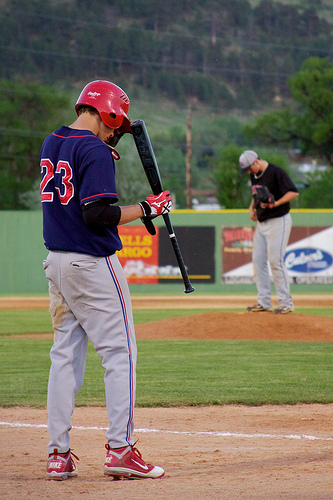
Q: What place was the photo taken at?
A: It was taken at the field.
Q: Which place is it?
A: It is a field.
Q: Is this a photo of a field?
A: Yes, it is showing a field.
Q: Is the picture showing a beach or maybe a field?
A: It is showing a field.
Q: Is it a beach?
A: No, it is a field.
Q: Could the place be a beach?
A: No, it is a field.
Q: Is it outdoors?
A: Yes, it is outdoors.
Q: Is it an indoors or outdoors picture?
A: It is outdoors.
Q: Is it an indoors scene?
A: No, it is outdoors.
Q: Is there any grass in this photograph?
A: Yes, there is grass.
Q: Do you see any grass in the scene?
A: Yes, there is grass.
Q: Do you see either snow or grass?
A: Yes, there is grass.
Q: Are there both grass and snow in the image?
A: No, there is grass but no snow.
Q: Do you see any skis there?
A: No, there are no skis.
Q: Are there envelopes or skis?
A: No, there are no skis or envelopes.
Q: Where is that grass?
A: The grass is on the ground.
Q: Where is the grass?
A: The grass is on the ground.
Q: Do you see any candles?
A: No, there are no candles.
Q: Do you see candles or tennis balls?
A: No, there are no candles or tennis balls.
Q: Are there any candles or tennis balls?
A: No, there are no candles or tennis balls.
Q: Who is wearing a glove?
A: The player is wearing a glove.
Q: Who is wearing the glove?
A: The player is wearing a glove.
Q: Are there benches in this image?
A: No, there are no benches.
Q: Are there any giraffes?
A: No, there are no giraffes.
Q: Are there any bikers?
A: No, there are no bikers.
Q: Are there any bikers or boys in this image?
A: No, there are no bikers or boys.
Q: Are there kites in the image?
A: No, there are no kites.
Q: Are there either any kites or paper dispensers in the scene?
A: No, there are no kites or paper dispensers.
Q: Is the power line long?
A: Yes, the power line is long.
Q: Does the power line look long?
A: Yes, the power line is long.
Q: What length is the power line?
A: The power line is long.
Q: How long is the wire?
A: The wire is long.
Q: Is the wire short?
A: No, the wire is long.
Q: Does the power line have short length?
A: No, the power line is long.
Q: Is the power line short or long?
A: The power line is long.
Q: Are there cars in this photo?
A: No, there are no cars.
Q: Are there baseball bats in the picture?
A: Yes, there is a baseball bat.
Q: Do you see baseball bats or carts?
A: Yes, there is a baseball bat.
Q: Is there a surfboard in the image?
A: No, there are no surfboards.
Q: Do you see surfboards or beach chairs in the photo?
A: No, there are no surfboards or beach chairs.